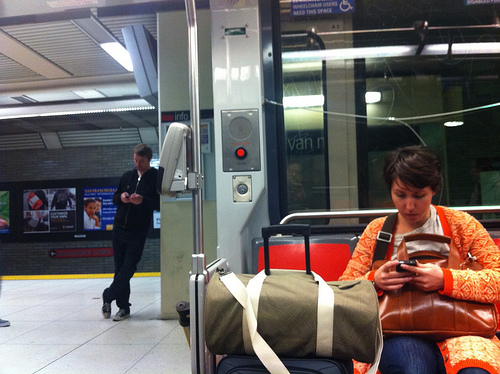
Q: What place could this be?
A: It is a station.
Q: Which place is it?
A: It is a station.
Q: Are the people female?
A: No, they are both male and female.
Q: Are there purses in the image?
A: Yes, there is a purse.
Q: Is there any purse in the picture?
A: Yes, there is a purse.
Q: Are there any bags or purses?
A: Yes, there is a purse.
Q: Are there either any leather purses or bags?
A: Yes, there is a leather purse.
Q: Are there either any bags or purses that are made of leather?
A: Yes, the purse is made of leather.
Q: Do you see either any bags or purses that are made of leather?
A: Yes, the purse is made of leather.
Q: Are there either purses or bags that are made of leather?
A: Yes, the purse is made of leather.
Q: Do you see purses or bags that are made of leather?
A: Yes, the purse is made of leather.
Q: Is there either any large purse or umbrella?
A: Yes, there is a large purse.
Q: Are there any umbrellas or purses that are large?
A: Yes, the purse is large.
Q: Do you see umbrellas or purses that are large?
A: Yes, the purse is large.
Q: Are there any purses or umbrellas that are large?
A: Yes, the purse is large.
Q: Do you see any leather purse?
A: Yes, there is a purse that is made of leather.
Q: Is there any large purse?
A: Yes, there is a large purse.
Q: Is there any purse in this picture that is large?
A: Yes, there is a purse that is large.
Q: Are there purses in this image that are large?
A: Yes, there is a purse that is large.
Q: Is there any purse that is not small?
A: Yes, there is a large purse.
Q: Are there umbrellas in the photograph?
A: No, there are no umbrellas.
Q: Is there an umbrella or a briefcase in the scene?
A: No, there are no umbrellas or briefcases.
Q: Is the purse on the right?
A: Yes, the purse is on the right of the image.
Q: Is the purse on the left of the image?
A: No, the purse is on the right of the image.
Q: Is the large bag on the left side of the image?
A: No, the purse is on the right of the image.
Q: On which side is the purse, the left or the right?
A: The purse is on the right of the image.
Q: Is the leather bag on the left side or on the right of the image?
A: The purse is on the right of the image.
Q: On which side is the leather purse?
A: The purse is on the right of the image.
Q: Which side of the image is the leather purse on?
A: The purse is on the right of the image.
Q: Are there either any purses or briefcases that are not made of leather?
A: No, there is a purse but it is made of leather.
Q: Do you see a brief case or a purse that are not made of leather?
A: No, there is a purse but it is made of leather.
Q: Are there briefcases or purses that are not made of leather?
A: No, there is a purse but it is made of leather.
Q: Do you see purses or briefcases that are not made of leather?
A: No, there is a purse but it is made of leather.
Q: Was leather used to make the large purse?
A: Yes, the purse is made of leather.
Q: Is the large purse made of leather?
A: Yes, the purse is made of leather.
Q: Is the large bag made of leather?
A: Yes, the purse is made of leather.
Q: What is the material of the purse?
A: The purse is made of leather.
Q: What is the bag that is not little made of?
A: The purse is made of leather.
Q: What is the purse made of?
A: The purse is made of leather.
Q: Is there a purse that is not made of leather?
A: No, there is a purse but it is made of leather.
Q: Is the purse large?
A: Yes, the purse is large.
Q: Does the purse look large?
A: Yes, the purse is large.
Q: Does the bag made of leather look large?
A: Yes, the purse is large.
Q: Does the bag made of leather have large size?
A: Yes, the purse is large.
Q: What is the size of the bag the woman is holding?
A: The purse is large.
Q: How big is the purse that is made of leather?
A: The purse is large.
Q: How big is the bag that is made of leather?
A: The purse is large.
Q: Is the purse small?
A: No, the purse is large.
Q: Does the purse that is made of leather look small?
A: No, the purse is large.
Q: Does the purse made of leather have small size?
A: No, the purse is large.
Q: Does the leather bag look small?
A: No, the purse is large.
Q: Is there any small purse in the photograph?
A: No, there is a purse but it is large.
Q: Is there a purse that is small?
A: No, there is a purse but it is large.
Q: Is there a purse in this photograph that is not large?
A: No, there is a purse but it is large.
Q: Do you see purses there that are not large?
A: No, there is a purse but it is large.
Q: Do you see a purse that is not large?
A: No, there is a purse but it is large.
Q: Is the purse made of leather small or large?
A: The purse is large.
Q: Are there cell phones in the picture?
A: Yes, there is a cell phone.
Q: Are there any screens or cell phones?
A: Yes, there is a cell phone.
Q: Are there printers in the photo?
A: No, there are no printers.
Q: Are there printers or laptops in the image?
A: No, there are no printers or laptops.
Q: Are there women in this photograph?
A: Yes, there is a woman.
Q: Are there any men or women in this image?
A: Yes, there is a woman.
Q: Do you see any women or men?
A: Yes, there is a woman.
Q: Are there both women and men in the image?
A: Yes, there are both a woman and a man.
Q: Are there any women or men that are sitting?
A: Yes, the woman is sitting.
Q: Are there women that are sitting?
A: Yes, there is a woman that is sitting.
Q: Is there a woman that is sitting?
A: Yes, there is a woman that is sitting.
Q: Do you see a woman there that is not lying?
A: Yes, there is a woman that is sitting .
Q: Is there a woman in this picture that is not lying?
A: Yes, there is a woman that is sitting.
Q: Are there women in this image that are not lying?
A: Yes, there is a woman that is sitting.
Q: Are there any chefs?
A: No, there are no chefs.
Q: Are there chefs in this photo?
A: No, there are no chefs.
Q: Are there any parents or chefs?
A: No, there are no chefs or parents.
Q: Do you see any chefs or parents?
A: No, there are no chefs or parents.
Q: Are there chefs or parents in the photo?
A: No, there are no chefs or parents.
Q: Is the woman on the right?
A: Yes, the woman is on the right of the image.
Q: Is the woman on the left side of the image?
A: No, the woman is on the right of the image.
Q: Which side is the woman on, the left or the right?
A: The woman is on the right of the image.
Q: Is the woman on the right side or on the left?
A: The woman is on the right of the image.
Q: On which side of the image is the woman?
A: The woman is on the right of the image.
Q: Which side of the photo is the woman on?
A: The woman is on the right of the image.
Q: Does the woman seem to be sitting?
A: Yes, the woman is sitting.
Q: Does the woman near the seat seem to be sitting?
A: Yes, the woman is sitting.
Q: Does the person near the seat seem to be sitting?
A: Yes, the woman is sitting.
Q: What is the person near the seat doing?
A: The woman is sitting.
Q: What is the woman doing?
A: The woman is sitting.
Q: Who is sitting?
A: The woman is sitting.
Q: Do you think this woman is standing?
A: No, the woman is sitting.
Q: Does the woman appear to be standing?
A: No, the woman is sitting.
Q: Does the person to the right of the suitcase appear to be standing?
A: No, the woman is sitting.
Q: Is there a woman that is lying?
A: No, there is a woman but she is sitting.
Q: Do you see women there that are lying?
A: No, there is a woman but she is sitting.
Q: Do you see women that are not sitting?
A: No, there is a woman but she is sitting.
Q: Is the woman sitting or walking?
A: The woman is sitting.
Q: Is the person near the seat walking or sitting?
A: The woman is sitting.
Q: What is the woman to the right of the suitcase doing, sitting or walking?
A: The woman is sitting.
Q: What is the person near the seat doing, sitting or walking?
A: The woman is sitting.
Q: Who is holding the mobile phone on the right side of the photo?
A: The woman is holding the cell phone.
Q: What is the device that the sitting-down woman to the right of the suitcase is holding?
A: The device is a cell phone.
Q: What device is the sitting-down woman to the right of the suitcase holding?
A: The woman is holding the cell phone.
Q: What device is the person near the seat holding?
A: The woman is holding the cell phone.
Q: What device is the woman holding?
A: The woman is holding the cell phone.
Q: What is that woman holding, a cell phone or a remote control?
A: The woman is holding a cell phone.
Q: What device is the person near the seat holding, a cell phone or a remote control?
A: The woman is holding a cell phone.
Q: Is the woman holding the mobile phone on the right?
A: Yes, the woman is holding the cell phone.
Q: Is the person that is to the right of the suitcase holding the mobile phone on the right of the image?
A: Yes, the woman is holding the cell phone.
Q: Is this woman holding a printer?
A: No, the woman is holding the cell phone.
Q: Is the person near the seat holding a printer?
A: No, the woman is holding the cell phone.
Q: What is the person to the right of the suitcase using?
A: The woman is using a cellphone.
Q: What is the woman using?
A: The woman is using a cellphone.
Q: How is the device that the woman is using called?
A: The device is a cell phone.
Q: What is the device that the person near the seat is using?
A: The device is a cell phone.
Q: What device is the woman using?
A: The woman is using a cell phone.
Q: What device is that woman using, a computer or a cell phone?
A: The woman is using a cell phone.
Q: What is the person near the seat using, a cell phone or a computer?
A: The woman is using a cell phone.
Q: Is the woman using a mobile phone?
A: Yes, the woman is using a mobile phone.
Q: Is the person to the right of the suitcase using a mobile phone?
A: Yes, the woman is using a mobile phone.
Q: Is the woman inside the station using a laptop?
A: No, the woman is using a mobile phone.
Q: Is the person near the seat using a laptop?
A: No, the woman is using a mobile phone.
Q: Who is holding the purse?
A: The woman is holding the purse.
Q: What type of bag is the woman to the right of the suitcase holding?
A: The woman is holding the purse.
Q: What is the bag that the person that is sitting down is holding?
A: The bag is a purse.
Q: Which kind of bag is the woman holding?
A: The woman is holding the purse.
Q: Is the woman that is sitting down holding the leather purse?
A: Yes, the woman is holding the purse.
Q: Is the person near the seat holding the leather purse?
A: Yes, the woman is holding the purse.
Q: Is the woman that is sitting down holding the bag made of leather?
A: Yes, the woman is holding the purse.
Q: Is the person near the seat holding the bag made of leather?
A: Yes, the woman is holding the purse.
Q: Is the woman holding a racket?
A: No, the woman is holding the purse.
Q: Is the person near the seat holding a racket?
A: No, the woman is holding the purse.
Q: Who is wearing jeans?
A: The woman is wearing jeans.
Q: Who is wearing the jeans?
A: The woman is wearing jeans.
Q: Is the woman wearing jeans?
A: Yes, the woman is wearing jeans.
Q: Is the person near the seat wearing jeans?
A: Yes, the woman is wearing jeans.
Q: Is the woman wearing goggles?
A: No, the woman is wearing jeans.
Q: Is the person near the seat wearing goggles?
A: No, the woman is wearing jeans.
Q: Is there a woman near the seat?
A: Yes, there is a woman near the seat.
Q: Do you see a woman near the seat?
A: Yes, there is a woman near the seat.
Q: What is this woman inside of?
A: The woman is inside the station.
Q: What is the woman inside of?
A: The woman is inside the station.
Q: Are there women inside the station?
A: Yes, there is a woman inside the station.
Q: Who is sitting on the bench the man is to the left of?
A: The woman is sitting on the bench.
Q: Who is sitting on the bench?
A: The woman is sitting on the bench.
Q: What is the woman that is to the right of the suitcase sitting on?
A: The woman is sitting on the bench.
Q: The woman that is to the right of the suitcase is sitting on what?
A: The woman is sitting on the bench.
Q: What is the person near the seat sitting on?
A: The woman is sitting on the bench.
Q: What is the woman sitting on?
A: The woman is sitting on the bench.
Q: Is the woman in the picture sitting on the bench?
A: Yes, the woman is sitting on the bench.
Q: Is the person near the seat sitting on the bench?
A: Yes, the woman is sitting on the bench.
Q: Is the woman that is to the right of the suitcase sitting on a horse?
A: No, the woman is sitting on the bench.